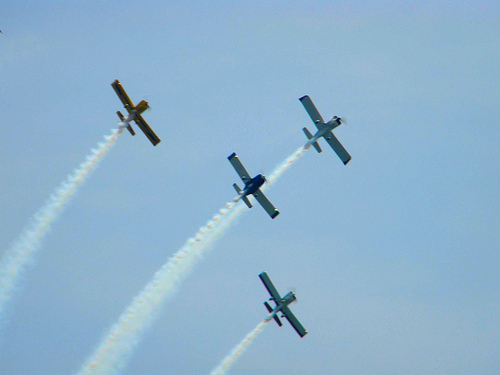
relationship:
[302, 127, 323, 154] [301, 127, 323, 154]
fin has fin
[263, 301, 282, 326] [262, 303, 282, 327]
fin has fin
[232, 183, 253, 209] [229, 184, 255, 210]
fin has fin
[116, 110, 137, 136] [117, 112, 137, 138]
fin has fin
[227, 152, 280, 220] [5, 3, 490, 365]
airplane flying in air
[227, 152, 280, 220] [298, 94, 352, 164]
airplane lined up behind airplane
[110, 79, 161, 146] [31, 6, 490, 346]
airplane in sky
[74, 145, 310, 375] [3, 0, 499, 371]
cloud in sky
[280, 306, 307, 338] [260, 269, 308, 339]
wing of plane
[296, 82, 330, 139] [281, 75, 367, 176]
wing of plane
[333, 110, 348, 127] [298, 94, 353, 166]
propellars on choppers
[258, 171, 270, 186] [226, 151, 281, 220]
propellars on choppers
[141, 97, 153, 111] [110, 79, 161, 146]
propellars on airplane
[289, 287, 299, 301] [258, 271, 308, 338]
propellars on airplane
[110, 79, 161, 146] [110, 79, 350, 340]
airplane in squadron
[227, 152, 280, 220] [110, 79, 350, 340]
airplane in squadron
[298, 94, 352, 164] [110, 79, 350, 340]
airplane in squadron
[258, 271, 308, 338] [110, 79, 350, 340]
airplane in squadron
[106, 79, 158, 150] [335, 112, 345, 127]
airplane has propeller engine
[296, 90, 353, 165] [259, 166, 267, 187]
airplane has propeller engine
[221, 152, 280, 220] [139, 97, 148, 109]
airplane has propeller engine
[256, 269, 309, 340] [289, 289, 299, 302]
airplane has propeller engine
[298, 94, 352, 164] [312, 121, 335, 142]
airplane has wheels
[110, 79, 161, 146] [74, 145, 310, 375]
airplane has cloud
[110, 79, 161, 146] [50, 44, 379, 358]
airplane in air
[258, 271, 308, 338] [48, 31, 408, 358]
airplane in air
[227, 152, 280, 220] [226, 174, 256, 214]
airplane has tail